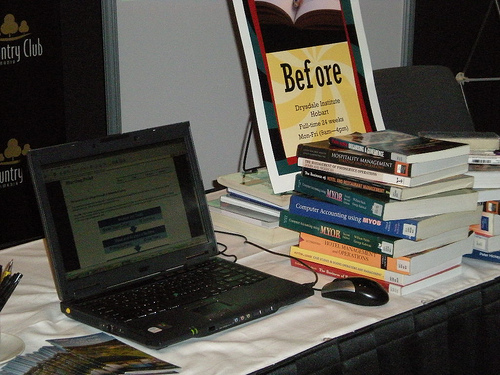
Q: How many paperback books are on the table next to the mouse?
A: 10.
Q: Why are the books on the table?
A: To read.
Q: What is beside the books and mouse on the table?
A: A laptop.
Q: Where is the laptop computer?
A: Top of the table.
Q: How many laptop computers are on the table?
A: 1.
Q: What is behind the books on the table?
A: A sign.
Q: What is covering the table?
A: A tablecloth.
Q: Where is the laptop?
A: On the desk.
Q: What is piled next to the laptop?
A: Books.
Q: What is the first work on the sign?
A: Before.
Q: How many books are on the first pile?
A: Ten.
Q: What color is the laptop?
A: Black.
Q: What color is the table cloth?
A: White.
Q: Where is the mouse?
A: On the table.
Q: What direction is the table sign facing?
A: Away from the wall.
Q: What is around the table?
A: Table skirt.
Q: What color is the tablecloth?
A: White.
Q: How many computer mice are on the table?
A: One.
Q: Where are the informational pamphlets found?
A: Left side.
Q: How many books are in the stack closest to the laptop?
A: Ten.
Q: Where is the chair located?
A: Right side.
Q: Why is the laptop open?
A: Being used.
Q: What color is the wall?
A: White.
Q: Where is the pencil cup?
A: Behind the pamphlets.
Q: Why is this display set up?
A: To provide information.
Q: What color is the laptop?
A: Black.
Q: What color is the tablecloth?
A: White.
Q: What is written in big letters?
A: Before.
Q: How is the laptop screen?
A: On.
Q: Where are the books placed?
A: Right side of the laptop.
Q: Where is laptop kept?
A: In the table.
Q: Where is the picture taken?
A: At the library.